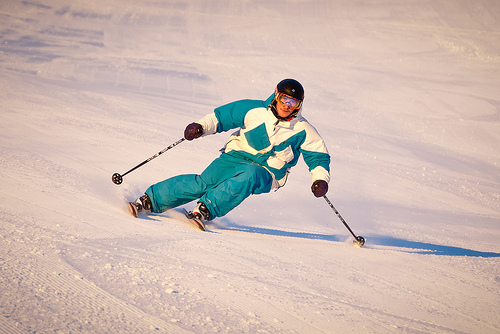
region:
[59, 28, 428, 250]
This man is skiing.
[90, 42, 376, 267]
The man is moving downhill.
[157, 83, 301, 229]
His jacket is turqoise and white.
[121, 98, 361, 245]
The man is holding poles.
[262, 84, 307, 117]
The man has goggles.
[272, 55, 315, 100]
The man has on a helmet.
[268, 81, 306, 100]
the man's helmet is black.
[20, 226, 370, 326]
The ground is made of snow.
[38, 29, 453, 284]
The snow is bright white.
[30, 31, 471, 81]
The snow looks very smooth.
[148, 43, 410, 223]
the woman is skiing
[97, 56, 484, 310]
woman is holding ski poles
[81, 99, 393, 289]
ski poles are black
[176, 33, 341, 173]
woman's jacket is green and white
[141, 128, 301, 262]
woman's pants are green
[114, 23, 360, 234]
woman is leaning side ways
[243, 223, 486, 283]
shadow of woman on ground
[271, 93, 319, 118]
woman is wearing goggles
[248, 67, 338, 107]
woman's hat is black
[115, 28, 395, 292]
woman is going downhill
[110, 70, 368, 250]
skier going down slope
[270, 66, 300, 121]
skier wearing black helmet and goggles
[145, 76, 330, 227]
skier in teal and white outfit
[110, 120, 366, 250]
gloved hands holding poles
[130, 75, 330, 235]
skier leaning heavily to left side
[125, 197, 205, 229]
edges of skis touching snow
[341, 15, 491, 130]
faint loops and curves on snow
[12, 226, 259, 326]
pieces of snow resting on surface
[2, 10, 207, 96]
light blue markings on the snow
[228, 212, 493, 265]
lean and tall shadow to side of skier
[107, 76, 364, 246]
a man skiing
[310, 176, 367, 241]
ski pole in a man's hand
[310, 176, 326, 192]
dark colored glove on a skiers hand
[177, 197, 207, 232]
skis attached to a man's foot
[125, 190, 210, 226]
two skis attached to a man's feet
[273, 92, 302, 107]
clear goggles covering the man's eyes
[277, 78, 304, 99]
black helmet on a man's head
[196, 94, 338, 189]
blue and white thick coat on a skier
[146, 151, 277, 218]
blue pants on a skier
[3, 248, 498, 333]
lots of marks and tracks on the snow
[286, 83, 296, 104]
part of an helmet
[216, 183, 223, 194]
edge of a knee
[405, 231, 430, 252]
part of a shadow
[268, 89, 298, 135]
face of a man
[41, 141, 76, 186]
part of the snow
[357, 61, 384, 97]
part of a slope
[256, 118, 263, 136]
blue patch on a jacket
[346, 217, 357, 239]
part of a pole